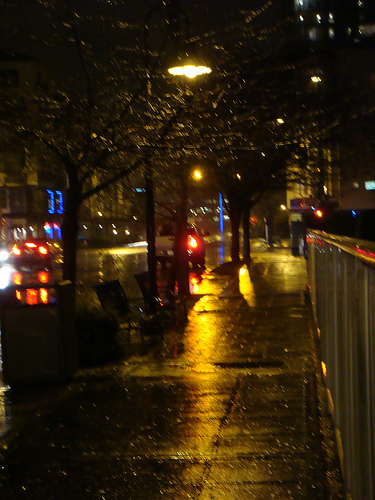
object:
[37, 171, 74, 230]
lights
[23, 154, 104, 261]
window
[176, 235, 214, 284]
lights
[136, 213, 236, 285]
car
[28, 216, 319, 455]
road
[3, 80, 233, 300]
building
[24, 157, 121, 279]
lights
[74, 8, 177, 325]
tree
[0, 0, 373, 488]
city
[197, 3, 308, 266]
tree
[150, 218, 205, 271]
truck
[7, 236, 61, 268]
car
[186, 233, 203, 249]
tail light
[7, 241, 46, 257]
tail lights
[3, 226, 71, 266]
truck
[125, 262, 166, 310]
can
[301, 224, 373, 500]
fence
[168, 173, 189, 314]
pole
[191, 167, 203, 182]
light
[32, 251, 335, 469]
sidewalk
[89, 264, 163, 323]
benches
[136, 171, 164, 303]
poles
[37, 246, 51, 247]
lights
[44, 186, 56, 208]
sign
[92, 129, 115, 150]
branches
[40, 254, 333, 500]
concrete